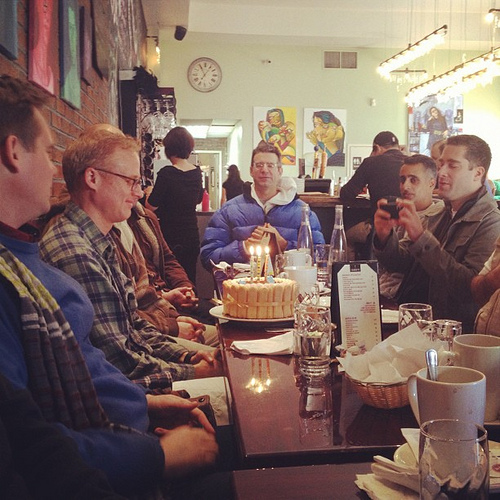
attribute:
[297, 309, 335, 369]
cup — white, glass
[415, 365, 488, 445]
cup — white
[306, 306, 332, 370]
glass — clear, shiny, half full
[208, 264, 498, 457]
table — brown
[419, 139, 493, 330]
person — seated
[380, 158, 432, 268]
person — seated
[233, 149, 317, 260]
person — seated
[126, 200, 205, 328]
person — seated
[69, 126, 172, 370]
person — seated, smiling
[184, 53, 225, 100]
clock — hanging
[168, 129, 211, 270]
woman — standing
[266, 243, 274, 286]
candle — lit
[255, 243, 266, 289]
candle — lit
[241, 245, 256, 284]
candle — lit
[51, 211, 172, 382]
shirt — plaid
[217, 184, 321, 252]
coat — blue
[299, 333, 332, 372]
liquid — clear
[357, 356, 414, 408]
basket — woven, empty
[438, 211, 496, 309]
coat — gray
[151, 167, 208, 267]
dress — black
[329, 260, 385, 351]
menu — propped, standing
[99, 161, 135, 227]
skin — light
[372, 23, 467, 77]
lights — hanging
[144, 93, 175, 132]
glasses — hanging